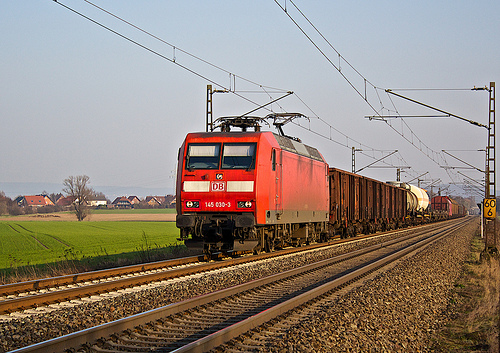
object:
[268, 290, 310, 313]
edge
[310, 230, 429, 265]
railroads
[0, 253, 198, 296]
rails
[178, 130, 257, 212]
train front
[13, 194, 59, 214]
homes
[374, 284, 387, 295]
pebbles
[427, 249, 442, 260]
pebbles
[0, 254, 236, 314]
train tracks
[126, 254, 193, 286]
track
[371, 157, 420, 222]
ground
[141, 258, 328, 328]
railroad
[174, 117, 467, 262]
train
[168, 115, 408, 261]
freight train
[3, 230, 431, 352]
tracks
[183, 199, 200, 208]
headlights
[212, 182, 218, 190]
letters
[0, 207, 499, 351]
ground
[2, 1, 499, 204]
sky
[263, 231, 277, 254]
wheel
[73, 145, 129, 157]
clouds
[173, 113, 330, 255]
engine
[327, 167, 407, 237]
train cars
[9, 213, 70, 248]
track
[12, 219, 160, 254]
field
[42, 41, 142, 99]
clouds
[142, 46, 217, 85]
lines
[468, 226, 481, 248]
sign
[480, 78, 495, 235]
electrical pole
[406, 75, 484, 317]
station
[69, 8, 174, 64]
wires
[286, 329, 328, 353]
gravel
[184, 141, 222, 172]
windows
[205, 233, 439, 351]
edge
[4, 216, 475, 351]
rail